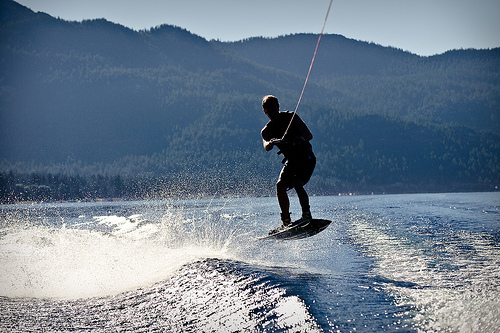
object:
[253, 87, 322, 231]
person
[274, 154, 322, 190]
shorts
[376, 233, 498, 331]
water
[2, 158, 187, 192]
vegetation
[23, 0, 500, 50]
sky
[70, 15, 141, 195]
mountain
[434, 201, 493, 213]
sunlight reflection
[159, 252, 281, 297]
sea foam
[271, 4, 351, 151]
string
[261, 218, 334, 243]
surfboard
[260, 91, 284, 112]
hair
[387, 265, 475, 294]
shadow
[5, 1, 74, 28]
top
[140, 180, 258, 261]
water droplets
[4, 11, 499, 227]
air